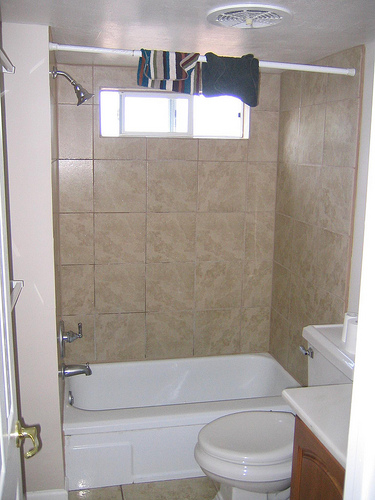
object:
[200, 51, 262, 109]
towel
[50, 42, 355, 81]
rod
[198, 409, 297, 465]
toilet cover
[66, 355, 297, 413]
tub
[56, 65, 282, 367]
wall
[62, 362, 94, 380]
faucet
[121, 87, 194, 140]
window